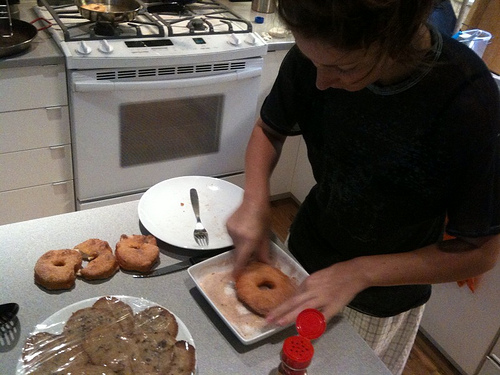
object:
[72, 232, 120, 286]
donuts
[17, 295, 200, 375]
plate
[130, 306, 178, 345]
cookies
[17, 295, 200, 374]
plastic wrap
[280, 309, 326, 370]
shaker top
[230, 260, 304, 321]
donut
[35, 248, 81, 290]
donut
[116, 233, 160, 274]
donut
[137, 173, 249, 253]
plate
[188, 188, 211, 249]
fork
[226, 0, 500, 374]
woman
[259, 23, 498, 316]
shirt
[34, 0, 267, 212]
stove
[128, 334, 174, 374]
cookie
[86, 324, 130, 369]
cookie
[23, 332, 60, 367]
cookie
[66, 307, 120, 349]
cookie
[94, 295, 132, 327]
cookie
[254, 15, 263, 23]
bottle cap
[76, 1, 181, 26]
skillet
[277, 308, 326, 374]
seasoning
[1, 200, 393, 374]
counter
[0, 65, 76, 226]
cabinets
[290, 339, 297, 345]
holes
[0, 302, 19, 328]
spatula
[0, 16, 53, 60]
pan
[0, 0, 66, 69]
counter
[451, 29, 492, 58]
container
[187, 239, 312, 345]
dish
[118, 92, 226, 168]
window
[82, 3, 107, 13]
donut